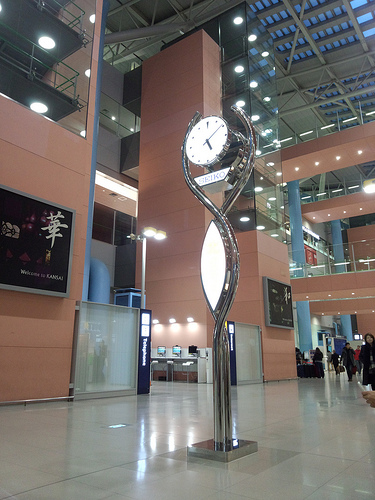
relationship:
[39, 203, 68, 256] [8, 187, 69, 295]
writing on wallpicture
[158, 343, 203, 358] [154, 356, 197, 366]
computers on table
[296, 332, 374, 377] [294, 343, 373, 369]
group of people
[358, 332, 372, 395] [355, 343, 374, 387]
woman dressed in black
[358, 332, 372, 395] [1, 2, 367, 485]
woman walking in mall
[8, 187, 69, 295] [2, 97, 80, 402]
sign hanging on wall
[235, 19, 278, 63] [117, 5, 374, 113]
lights embedded in ceiling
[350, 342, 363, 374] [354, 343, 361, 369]
person dressed in red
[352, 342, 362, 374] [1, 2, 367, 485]
prson walking in mall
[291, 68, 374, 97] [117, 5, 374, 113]
girders in ceiling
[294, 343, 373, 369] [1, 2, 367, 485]
people walking thru building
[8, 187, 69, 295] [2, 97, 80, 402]
advertisng board attached to wall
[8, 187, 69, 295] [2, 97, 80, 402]
advertising board attached to wall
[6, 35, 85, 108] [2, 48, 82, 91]
walkway on secondfloor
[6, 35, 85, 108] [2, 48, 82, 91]
safetyrail on secondfloor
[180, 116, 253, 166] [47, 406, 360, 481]
clock on floor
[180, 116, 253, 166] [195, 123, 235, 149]
clock has oranments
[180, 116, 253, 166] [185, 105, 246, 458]
clock with steelframe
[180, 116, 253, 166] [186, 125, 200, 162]
clock has cardinal numbers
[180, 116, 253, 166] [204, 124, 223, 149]
clock displays 5.10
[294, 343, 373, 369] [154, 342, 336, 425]
people on hallway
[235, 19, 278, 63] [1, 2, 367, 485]
lights in building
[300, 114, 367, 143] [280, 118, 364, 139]
bridge with rails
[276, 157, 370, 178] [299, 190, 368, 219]
lights below bridge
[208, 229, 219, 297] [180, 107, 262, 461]
light in clocktower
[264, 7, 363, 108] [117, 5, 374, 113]
sunlights on roof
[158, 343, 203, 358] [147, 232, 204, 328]
computers on wall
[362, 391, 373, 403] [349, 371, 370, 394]
hand holding phone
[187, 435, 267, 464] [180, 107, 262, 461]
base of clocktower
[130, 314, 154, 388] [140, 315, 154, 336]
towers with light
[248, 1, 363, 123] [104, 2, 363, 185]
skylight built into ceiling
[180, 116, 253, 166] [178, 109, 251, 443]
clock mounted on bar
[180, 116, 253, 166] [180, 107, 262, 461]
clock mounted on clocktower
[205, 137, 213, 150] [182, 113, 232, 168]
hourhand mounted on clock